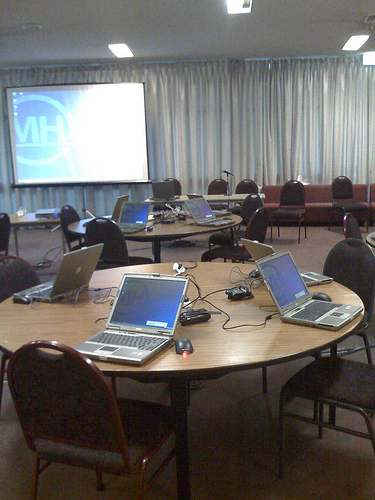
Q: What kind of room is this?
A: Conference room.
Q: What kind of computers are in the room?
A: Laptops.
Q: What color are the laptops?
A: Silver.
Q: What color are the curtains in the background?
A: White.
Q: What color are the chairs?
A: Grey.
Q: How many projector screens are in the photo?
A: One.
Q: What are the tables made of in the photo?
A: Wood.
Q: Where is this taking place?
A: At a conference.